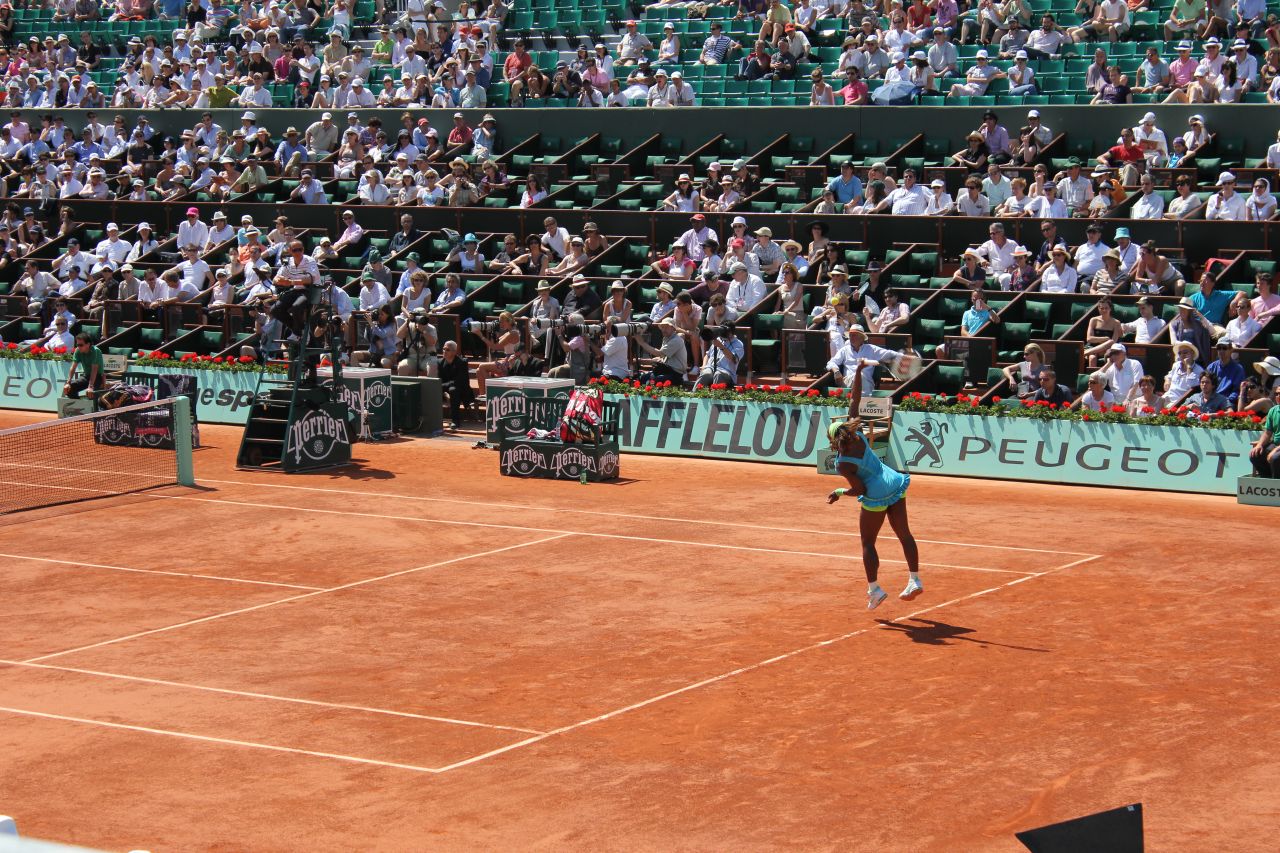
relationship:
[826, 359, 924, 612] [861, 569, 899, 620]
man wearing shoe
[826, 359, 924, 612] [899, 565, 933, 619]
man wearing shoe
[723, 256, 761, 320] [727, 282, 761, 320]
man wearing shirt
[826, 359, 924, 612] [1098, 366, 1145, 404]
man wearing shirt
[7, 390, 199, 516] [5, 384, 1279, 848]
net on tennis court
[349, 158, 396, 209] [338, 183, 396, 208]
man wearing shirt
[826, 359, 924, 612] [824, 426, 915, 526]
man wearing blue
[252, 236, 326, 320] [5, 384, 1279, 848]
chair umpire in th tennis court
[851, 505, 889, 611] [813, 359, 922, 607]
leg of tennis player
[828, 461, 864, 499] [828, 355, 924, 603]
arm of tennis player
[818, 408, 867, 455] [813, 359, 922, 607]
head of tennis player